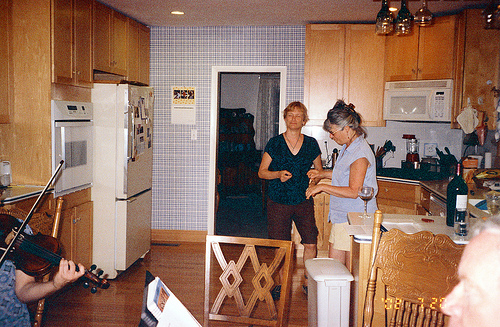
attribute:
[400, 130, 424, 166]
blender — red, electric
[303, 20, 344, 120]
cabinet door — brown, wooden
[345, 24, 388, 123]
cabinet door — wooden, brown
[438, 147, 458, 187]
knife block — wooden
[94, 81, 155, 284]
fridge — white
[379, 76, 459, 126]
microwave — white, built-in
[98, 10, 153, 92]
cabinets — brown, high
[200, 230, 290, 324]
kitchen chair — brown, wooden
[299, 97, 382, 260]
woman — dancing, grey-haired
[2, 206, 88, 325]
person — sitting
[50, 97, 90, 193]
oven — mounted, white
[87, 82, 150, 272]
refrigerator — white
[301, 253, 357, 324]
trash can — white, plastic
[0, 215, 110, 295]
violin — brown, wood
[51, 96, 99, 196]
oven — white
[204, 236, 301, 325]
chair — wooden, brown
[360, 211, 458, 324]
chair — brown, wooden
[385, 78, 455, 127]
microwave — white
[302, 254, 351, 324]
trash bin — white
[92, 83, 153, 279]
refrigerator — white, large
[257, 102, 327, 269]
woman — brown haired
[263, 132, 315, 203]
shirt — blue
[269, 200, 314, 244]
shorts — brown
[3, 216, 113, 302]
violin — brown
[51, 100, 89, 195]
stove — white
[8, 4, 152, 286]
wall — brown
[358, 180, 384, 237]
wine glass — nearly empty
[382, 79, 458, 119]
microwave — white, above-the-range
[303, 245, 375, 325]
trash can — white, plastic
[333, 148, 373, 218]
shirt — gray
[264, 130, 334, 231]
shirt — green, black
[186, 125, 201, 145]
light switch — white